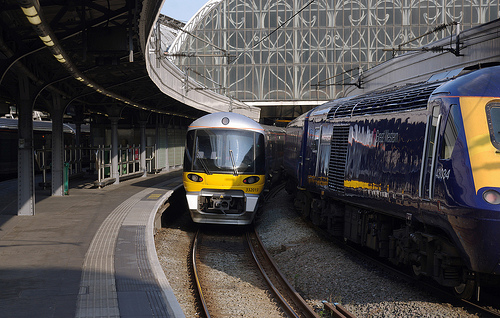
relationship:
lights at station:
[19, 14, 198, 138] [3, 96, 164, 300]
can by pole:
[56, 159, 87, 190] [45, 105, 66, 196]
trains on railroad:
[191, 100, 469, 250] [204, 240, 310, 308]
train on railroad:
[177, 111, 305, 225] [204, 240, 310, 308]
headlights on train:
[179, 166, 277, 207] [177, 111, 305, 225]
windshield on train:
[190, 131, 264, 167] [177, 111, 305, 225]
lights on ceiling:
[19, 14, 198, 138] [84, 25, 151, 81]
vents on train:
[321, 123, 346, 190] [177, 111, 305, 225]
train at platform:
[177, 111, 305, 225] [94, 159, 180, 316]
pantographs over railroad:
[183, 250, 295, 316] [190, 228, 320, 317]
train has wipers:
[177, 102, 289, 228] [199, 135, 255, 192]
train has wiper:
[177, 102, 289, 228] [217, 130, 239, 174]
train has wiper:
[177, 102, 289, 228] [184, 131, 204, 173]